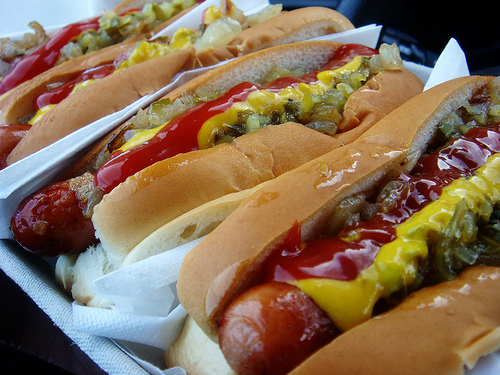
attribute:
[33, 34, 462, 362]
hotdogs — fresh, snack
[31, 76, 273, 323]
line — hotdogs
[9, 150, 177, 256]
hotdog — topped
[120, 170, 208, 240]
bun — wet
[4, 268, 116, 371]
plate — white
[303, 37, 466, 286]
food — hotdog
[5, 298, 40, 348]
table — black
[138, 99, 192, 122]
onions — chopped